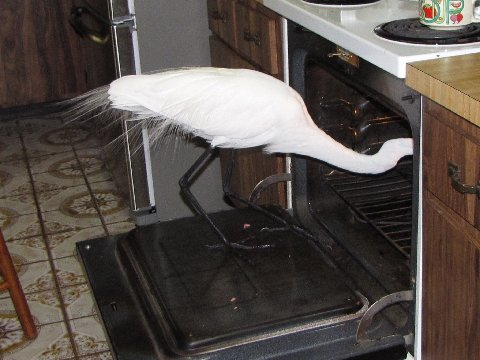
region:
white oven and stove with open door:
[73, 1, 478, 358]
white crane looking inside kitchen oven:
[48, 65, 412, 252]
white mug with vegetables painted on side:
[419, 0, 478, 30]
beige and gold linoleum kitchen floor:
[1, 114, 138, 358]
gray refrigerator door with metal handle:
[94, 0, 235, 229]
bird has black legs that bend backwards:
[179, 147, 318, 255]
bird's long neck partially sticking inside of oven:
[296, 116, 413, 174]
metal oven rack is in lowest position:
[318, 166, 418, 257]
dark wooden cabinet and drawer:
[418, 110, 478, 358]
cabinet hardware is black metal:
[444, 159, 478, 195]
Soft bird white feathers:
[49, 65, 136, 182]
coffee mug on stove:
[415, 0, 478, 40]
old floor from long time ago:
[22, 173, 87, 231]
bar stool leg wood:
[0, 236, 48, 341]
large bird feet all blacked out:
[194, 200, 311, 297]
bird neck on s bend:
[338, 131, 416, 185]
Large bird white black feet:
[87, 60, 399, 260]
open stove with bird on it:
[69, 180, 415, 358]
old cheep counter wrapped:
[403, 37, 475, 119]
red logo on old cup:
[420, 5, 444, 25]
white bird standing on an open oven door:
[82, 48, 410, 290]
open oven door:
[104, 207, 369, 351]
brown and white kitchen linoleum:
[4, 149, 118, 234]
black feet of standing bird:
[168, 137, 324, 285]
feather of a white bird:
[76, 42, 259, 154]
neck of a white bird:
[302, 101, 413, 186]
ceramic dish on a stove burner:
[403, 0, 478, 45]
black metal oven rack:
[333, 169, 420, 252]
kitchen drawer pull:
[436, 150, 477, 209]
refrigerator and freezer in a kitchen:
[71, 3, 184, 210]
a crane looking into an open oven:
[75, 59, 419, 271]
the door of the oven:
[70, 201, 420, 358]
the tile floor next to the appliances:
[5, 109, 122, 353]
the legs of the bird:
[176, 144, 317, 261]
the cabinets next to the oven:
[416, 99, 479, 359]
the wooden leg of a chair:
[1, 238, 35, 340]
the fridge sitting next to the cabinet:
[63, 3, 226, 210]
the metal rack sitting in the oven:
[330, 165, 421, 259]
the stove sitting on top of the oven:
[269, 2, 477, 74]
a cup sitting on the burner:
[413, 2, 478, 34]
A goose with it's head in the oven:
[49, 47, 398, 257]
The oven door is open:
[66, 181, 397, 357]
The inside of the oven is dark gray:
[114, 251, 319, 331]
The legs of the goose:
[170, 155, 346, 268]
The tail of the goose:
[104, 68, 158, 132]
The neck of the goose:
[313, 117, 380, 182]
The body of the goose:
[172, 54, 295, 160]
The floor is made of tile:
[14, 146, 79, 231]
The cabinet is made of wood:
[424, 148, 471, 355]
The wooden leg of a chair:
[0, 216, 46, 349]